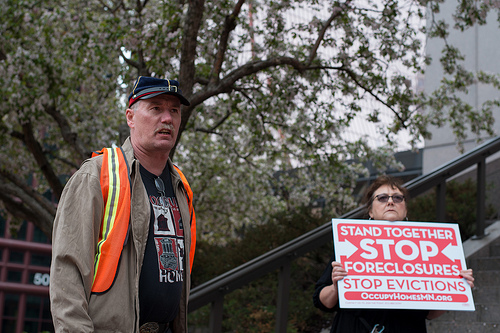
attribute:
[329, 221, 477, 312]
sign — square, red, white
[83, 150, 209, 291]
jacket — orange, tan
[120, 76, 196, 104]
hat — blue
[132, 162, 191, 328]
shirt — black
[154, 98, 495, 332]
railing — metal, black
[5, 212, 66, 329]
bars — red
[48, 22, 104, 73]
leaves — green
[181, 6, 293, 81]
limbs — brown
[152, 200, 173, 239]
square — red, white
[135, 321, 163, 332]
buckle — metal, oval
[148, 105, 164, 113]
eye — open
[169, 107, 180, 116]
eye — open